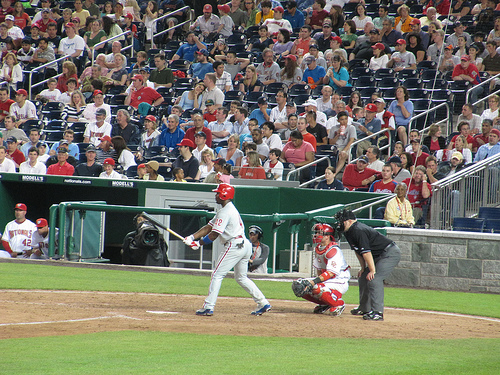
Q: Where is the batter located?
A: Batting plate.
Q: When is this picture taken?
A: During a game.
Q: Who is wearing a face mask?
A: Catcher.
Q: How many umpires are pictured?
A: One.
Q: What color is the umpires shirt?
A: Black.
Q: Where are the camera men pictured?
A: Dugout.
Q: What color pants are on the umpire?
A: Grey.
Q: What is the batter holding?
A: A bat.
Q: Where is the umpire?
A: Behind the catcher.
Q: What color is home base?
A: White.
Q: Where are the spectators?
A: In the bleacher seats.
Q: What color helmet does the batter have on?
A: Red.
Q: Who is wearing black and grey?
A: The umpire.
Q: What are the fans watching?
A: A baseball game.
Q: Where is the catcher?
A: Behind the batter.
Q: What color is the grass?
A: Green.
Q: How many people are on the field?
A: Three.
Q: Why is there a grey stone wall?
A: For dividing.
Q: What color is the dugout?
A: Dark green.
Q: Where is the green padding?
A: On railing.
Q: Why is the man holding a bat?
A: To hit the ball.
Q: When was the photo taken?
A: During a game.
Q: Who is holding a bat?
A: The hitter.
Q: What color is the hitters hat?
A: Red.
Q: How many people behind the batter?
A: Two.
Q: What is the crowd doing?
A: Watching baseball.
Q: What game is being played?
A: Baseball.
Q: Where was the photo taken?
A: In a park.